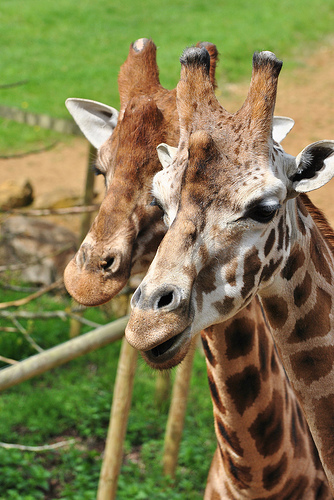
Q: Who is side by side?
A: Two giraffes.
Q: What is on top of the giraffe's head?
A: A set of horns.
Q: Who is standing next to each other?
A: Two giraffes.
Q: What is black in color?
A: The giraffe's eyes.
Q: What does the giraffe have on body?
A: Spots.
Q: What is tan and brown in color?
A: The giraffe.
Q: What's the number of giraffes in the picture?
A: 2.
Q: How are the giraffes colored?
A: White with brown spots.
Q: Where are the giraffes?
A: Zoo.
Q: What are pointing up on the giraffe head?
A: Horns.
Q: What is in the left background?
A: Fence.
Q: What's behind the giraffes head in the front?
A: Another giraffe head.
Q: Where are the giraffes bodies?
A: Outside the picture.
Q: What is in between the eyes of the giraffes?
A: A lump.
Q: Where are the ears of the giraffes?
A: Below the horns and behind the eyes.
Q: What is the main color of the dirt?
A: Brown.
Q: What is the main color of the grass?
A: Green.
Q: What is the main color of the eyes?
A: Black.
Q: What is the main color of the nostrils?
A: Black.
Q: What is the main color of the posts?
A: Brown.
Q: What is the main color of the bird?
A: Brown.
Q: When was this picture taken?
A: Day time.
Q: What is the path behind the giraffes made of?
A: Dirt.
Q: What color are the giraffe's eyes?
A: Black.